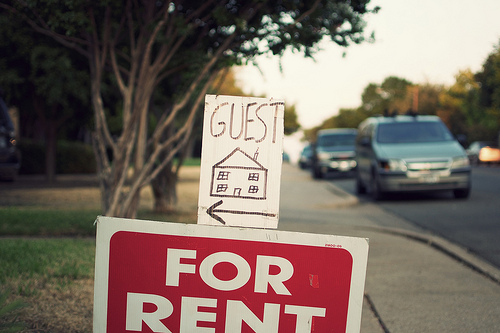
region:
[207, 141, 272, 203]
House draw on paper.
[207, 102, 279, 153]
Word GUEST written on paper.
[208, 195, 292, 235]
Arrow drawn on paper.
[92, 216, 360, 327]
Red and white sign in the ground.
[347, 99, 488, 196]
Van driving down the road.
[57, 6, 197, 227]
Trees in the ground.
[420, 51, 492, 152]
Trees still across the road.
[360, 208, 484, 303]
Sidewalk curving around road.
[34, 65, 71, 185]
Long pole in the ground.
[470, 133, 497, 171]
Car parked on the other side of road.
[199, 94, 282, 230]
Guest sign pointing to the left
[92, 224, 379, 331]
A sign advertising a house for rent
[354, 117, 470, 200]
A minivan parked on a street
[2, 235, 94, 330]
Grasslands next to the curb of the street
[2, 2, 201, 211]
A tree is behind the for rent signs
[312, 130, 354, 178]
A minivan is parked on the street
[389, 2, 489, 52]
The sky is bright during daytime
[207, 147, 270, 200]
A drawing of a house on a sign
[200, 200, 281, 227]
An arrow on a sign indicates the left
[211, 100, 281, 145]
A guest word is on a sign.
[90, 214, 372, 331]
Red and white for rent sign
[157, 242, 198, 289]
Letter F of the for rent sign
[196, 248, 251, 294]
Letter O of the for rent sign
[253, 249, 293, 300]
Letter R of the for rent sign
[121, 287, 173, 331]
Letter R of the for rent sign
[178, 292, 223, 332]
Letter E of the for rent sign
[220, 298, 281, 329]
Letter N of the for rent sign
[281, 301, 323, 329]
Letter T of the for rent sign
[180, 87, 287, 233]
sign pointing way for guests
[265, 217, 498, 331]
sidewalk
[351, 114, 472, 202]
Car parked along street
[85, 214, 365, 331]
Red and white For Rent sign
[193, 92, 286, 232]
Hand written sign on regular sign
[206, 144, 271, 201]
Hand drawn house on sign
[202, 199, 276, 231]
Hand drawn directional arrow on sign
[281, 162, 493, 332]
Cement sidewalk along road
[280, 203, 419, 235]
Cement driveway entrance ramp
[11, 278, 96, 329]
Dried grass on lawn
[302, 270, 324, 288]
Tape scar on sign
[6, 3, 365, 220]
Tree in front yard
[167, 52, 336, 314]
A white sign is next to the street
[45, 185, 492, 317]
The red and white for rent sign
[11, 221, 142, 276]
grass is behind the sign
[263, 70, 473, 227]
cars are parked on the street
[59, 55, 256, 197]
trees are in the background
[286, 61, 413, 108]
The sun is shining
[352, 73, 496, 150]
Green trees are in the distance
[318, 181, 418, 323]
the sidewalk is gray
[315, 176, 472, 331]
cracks are in the sidewalk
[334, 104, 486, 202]
A minivan is parked on the street